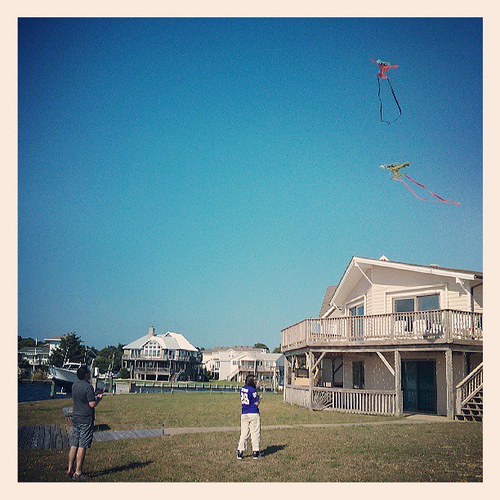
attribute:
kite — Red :
[370, 54, 405, 126]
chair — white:
[399, 307, 416, 333]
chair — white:
[417, 314, 437, 340]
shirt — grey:
[68, 377, 102, 415]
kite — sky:
[381, 160, 464, 207]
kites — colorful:
[366, 55, 464, 209]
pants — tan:
[235, 412, 260, 452]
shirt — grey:
[73, 387, 103, 411]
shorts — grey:
[57, 417, 112, 457]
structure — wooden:
[278, 258, 481, 418]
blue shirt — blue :
[239, 382, 261, 413]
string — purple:
[401, 172, 465, 209]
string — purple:
[392, 173, 431, 205]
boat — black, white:
[42, 358, 115, 398]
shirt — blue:
[230, 371, 267, 418]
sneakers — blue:
[234, 449, 262, 461]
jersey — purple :
[230, 382, 264, 417]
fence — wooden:
[282, 380, 396, 417]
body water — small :
[17, 374, 242, 401]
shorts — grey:
[67, 421, 96, 448]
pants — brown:
[237, 413, 262, 452]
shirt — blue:
[236, 385, 263, 415]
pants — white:
[236, 407, 264, 456]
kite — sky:
[369, 56, 404, 123]